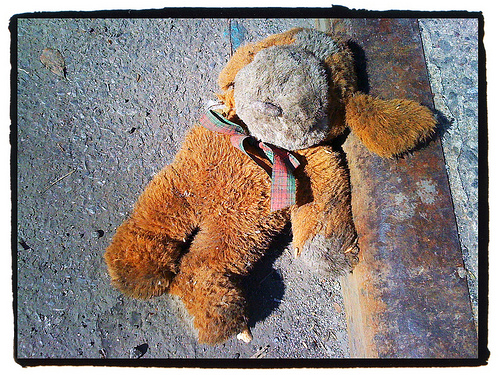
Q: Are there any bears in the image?
A: Yes, there is a bear.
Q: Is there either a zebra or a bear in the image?
A: Yes, there is a bear.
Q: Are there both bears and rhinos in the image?
A: No, there is a bear but no rhinos.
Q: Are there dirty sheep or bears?
A: Yes, there is a dirty bear.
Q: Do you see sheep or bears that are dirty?
A: Yes, the bear is dirty.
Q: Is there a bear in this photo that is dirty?
A: Yes, there is a dirty bear.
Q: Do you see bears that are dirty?
A: Yes, there is a bear that is dirty.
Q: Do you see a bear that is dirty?
A: Yes, there is a bear that is dirty.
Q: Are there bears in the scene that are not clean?
A: Yes, there is a dirty bear.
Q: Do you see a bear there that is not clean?
A: Yes, there is a dirty bear.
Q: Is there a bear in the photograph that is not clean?
A: Yes, there is a dirty bear.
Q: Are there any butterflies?
A: No, there are no butterflies.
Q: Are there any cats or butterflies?
A: No, there are no butterflies or cats.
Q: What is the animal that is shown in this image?
A: The animal is a bear.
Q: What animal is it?
A: The animal is a bear.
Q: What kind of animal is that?
A: This is a bear.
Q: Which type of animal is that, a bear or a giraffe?
A: This is a bear.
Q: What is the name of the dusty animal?
A: The animal is a bear.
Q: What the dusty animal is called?
A: The animal is a bear.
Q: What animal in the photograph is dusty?
A: The animal is a bear.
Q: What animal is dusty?
A: The animal is a bear.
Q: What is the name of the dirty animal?
A: The animal is a bear.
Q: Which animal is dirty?
A: The animal is a bear.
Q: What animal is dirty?
A: The animal is a bear.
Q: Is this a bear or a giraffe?
A: This is a bear.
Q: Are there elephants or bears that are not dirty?
A: No, there is a bear but it is dirty.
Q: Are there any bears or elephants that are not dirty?
A: No, there is a bear but it is dirty.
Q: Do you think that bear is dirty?
A: Yes, the bear is dirty.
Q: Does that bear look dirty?
A: Yes, the bear is dirty.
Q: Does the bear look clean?
A: No, the bear is dirty.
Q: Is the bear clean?
A: No, the bear is dirty.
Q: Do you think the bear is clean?
A: No, the bear is dirty.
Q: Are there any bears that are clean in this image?
A: No, there is a bear but it is dirty.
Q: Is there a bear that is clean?
A: No, there is a bear but it is dirty.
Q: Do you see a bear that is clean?
A: No, there is a bear but it is dirty.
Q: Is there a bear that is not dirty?
A: No, there is a bear but it is dirty.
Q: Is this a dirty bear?
A: Yes, this is a dirty bear.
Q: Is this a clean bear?
A: No, this is a dirty bear.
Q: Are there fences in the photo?
A: No, there are no fences.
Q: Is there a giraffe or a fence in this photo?
A: No, there are no fences or giraffes.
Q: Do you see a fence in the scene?
A: No, there are no fences.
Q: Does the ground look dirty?
A: Yes, the ground is dirty.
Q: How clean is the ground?
A: The ground is dirty.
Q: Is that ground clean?
A: No, the ground is dirty.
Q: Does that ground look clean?
A: No, the ground is dirty.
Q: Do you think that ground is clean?
A: No, the ground is dirty.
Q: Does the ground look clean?
A: No, the ground is dirty.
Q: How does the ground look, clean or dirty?
A: The ground is dirty.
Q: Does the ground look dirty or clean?
A: The ground is dirty.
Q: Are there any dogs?
A: No, there are no dogs.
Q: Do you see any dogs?
A: No, there are no dogs.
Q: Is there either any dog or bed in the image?
A: No, there are no dogs or beds.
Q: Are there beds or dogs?
A: No, there are no dogs or beds.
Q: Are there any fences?
A: No, there are no fences.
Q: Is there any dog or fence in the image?
A: No, there are no fences or dogs.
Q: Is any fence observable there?
A: No, there are no fences.